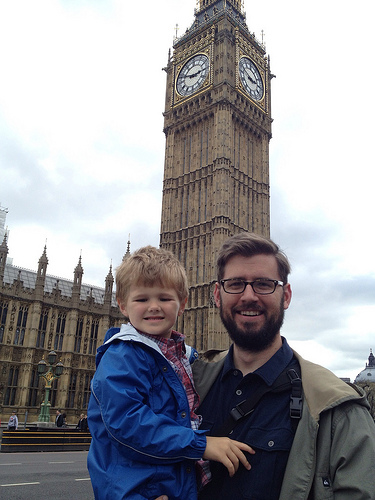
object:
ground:
[244, 119, 300, 149]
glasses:
[227, 269, 288, 301]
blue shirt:
[198, 372, 286, 485]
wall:
[1, 292, 88, 420]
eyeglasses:
[216, 276, 287, 293]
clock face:
[175, 61, 213, 95]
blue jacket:
[95, 322, 205, 498]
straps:
[221, 361, 303, 440]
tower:
[147, 0, 271, 349]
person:
[76, 412, 91, 427]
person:
[52, 405, 67, 425]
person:
[6, 411, 18, 428]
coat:
[85, 320, 215, 498]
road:
[2, 449, 95, 497]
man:
[181, 233, 370, 498]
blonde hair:
[109, 245, 189, 303]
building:
[0, 0, 278, 426]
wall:
[172, 158, 284, 240]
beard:
[214, 286, 285, 355]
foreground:
[65, 272, 349, 488]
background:
[5, 378, 90, 446]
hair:
[215, 235, 287, 261]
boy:
[93, 244, 208, 480]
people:
[2, 408, 90, 436]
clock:
[171, 54, 216, 95]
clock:
[237, 54, 270, 104]